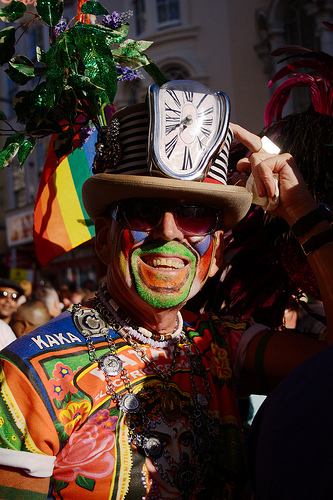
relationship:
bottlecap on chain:
[74, 309, 114, 335] [99, 366, 135, 389]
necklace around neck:
[125, 353, 185, 367] [132, 316, 190, 333]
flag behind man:
[48, 158, 84, 185] [11, 111, 256, 417]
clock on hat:
[164, 67, 224, 174] [82, 77, 251, 205]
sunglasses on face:
[127, 199, 203, 231] [129, 206, 202, 311]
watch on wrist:
[286, 193, 331, 220] [279, 186, 308, 211]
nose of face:
[156, 229, 183, 243] [129, 206, 202, 311]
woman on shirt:
[141, 403, 203, 487] [14, 335, 226, 488]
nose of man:
[156, 229, 183, 243] [11, 111, 256, 417]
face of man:
[129, 206, 202, 311] [11, 111, 256, 417]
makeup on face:
[121, 273, 172, 294] [129, 206, 202, 311]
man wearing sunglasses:
[11, 111, 256, 417] [127, 199, 203, 231]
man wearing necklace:
[11, 111, 256, 417] [125, 353, 185, 367]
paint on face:
[173, 249, 185, 257] [129, 206, 202, 311]